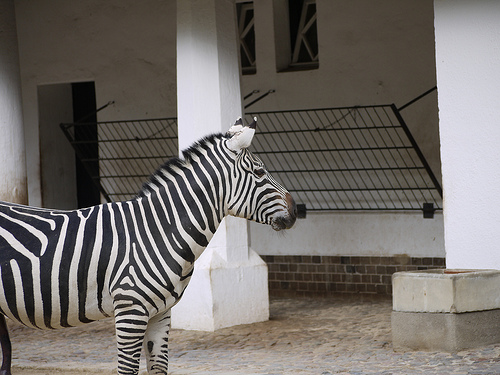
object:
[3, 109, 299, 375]
zebra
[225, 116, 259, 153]
white ears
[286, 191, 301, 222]
brown nose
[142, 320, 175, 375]
striped legs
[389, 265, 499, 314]
blocks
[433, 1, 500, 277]
post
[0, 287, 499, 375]
ground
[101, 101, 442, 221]
grills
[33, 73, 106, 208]
doorway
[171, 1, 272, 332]
pillar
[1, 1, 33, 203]
post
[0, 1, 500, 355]
building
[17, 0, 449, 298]
wall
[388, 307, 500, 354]
bricks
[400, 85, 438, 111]
pole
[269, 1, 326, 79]
window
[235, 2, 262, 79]
window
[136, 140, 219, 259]
neck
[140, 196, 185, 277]
stripes